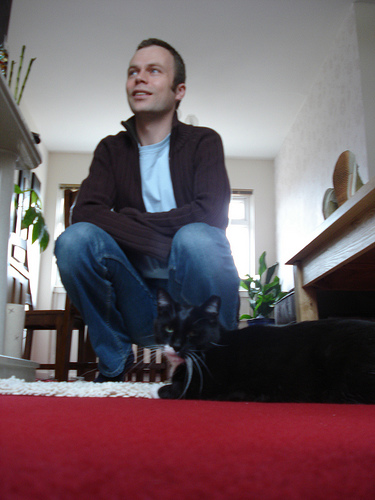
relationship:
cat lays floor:
[155, 292, 362, 395] [3, 377, 363, 490]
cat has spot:
[155, 292, 362, 395] [180, 353, 198, 360]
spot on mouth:
[180, 353, 198, 360] [180, 346, 209, 379]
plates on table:
[310, 148, 360, 218] [272, 184, 362, 325]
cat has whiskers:
[152, 286, 375, 405] [179, 339, 232, 394]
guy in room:
[52, 34, 253, 376] [4, 6, 363, 487]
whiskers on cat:
[178, 342, 212, 396] [150, 288, 372, 403]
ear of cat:
[195, 293, 222, 325] [150, 288, 372, 403]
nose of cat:
[171, 336, 185, 352] [150, 288, 372, 403]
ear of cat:
[152, 284, 175, 313] [150, 288, 372, 403]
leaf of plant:
[257, 250, 270, 285] [238, 247, 281, 326]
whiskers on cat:
[178, 349, 213, 399] [150, 288, 372, 403]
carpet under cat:
[0, 393, 372, 497] [150, 288, 372, 403]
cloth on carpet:
[0, 372, 170, 397] [0, 393, 372, 497]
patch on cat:
[160, 342, 179, 356] [150, 288, 372, 403]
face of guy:
[127, 44, 176, 112] [53, 37, 241, 381]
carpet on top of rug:
[0, 393, 374, 500] [2, 393, 374, 497]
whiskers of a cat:
[103, 332, 172, 377] [109, 285, 373, 404]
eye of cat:
[161, 323, 173, 335] [109, 285, 373, 404]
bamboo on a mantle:
[13, 45, 26, 100] [0, 71, 43, 172]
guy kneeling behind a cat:
[53, 37, 241, 381] [150, 288, 372, 403]